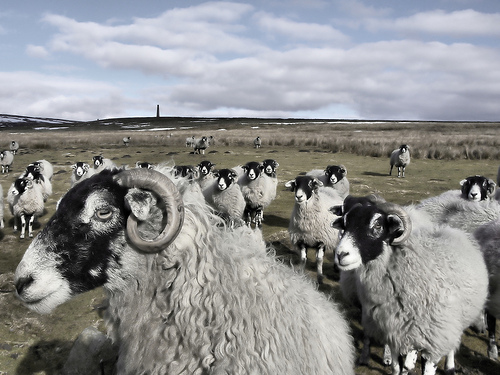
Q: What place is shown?
A: It is a field.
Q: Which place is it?
A: It is a field.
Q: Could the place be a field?
A: Yes, it is a field.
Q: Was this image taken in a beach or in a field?
A: It was taken at a field.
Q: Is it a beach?
A: No, it is a field.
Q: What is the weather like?
A: It is cloudy.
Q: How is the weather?
A: It is cloudy.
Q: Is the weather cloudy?
A: Yes, it is cloudy.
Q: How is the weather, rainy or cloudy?
A: It is cloudy.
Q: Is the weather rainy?
A: No, it is cloudy.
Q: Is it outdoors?
A: Yes, it is outdoors.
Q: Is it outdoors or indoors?
A: It is outdoors.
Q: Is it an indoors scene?
A: No, it is outdoors.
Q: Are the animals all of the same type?
A: Yes, all the animals are sheep.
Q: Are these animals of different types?
A: No, all the animals are sheep.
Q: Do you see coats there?
A: Yes, there is a coat.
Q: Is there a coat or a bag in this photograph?
A: Yes, there is a coat.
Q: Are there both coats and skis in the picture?
A: No, there is a coat but no skis.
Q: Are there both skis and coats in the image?
A: No, there is a coat but no skis.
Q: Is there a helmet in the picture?
A: No, there are no helmets.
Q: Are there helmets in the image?
A: No, there are no helmets.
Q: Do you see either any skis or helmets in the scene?
A: No, there are no helmets or skis.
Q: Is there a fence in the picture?
A: No, there are no fences.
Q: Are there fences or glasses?
A: No, there are no fences or glasses.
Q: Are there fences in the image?
A: No, there are no fences.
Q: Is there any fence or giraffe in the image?
A: No, there are no fences or giraffes.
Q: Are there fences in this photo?
A: No, there are no fences.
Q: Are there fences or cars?
A: No, there are no fences or cars.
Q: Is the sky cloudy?
A: Yes, the sky is cloudy.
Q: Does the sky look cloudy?
A: Yes, the sky is cloudy.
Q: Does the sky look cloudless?
A: No, the sky is cloudy.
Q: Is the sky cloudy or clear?
A: The sky is cloudy.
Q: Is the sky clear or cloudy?
A: The sky is cloudy.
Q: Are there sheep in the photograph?
A: Yes, there is a sheep.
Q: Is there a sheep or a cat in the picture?
A: Yes, there is a sheep.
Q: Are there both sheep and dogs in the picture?
A: No, there is a sheep but no dogs.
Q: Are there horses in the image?
A: No, there are no horses.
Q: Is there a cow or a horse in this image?
A: No, there are no horses or cows.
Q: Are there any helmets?
A: No, there are no helmets.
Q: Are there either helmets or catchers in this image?
A: No, there are no helmets or catchers.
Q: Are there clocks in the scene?
A: No, there are no clocks.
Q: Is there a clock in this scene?
A: No, there are no clocks.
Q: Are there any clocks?
A: No, there are no clocks.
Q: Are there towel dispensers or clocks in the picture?
A: No, there are no clocks or towel dispensers.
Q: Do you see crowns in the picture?
A: No, there are no crowns.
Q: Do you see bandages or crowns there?
A: No, there are no crowns or bandages.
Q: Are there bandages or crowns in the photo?
A: No, there are no crowns or bandages.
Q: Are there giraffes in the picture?
A: No, there are no giraffes.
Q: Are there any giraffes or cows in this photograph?
A: No, there are no giraffes or cows.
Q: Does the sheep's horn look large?
A: Yes, the horn is large.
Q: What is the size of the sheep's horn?
A: The horn is large.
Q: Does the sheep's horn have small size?
A: No, the horn is large.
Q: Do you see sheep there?
A: Yes, there is a sheep.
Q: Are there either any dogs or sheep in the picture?
A: Yes, there is a sheep.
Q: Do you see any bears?
A: No, there are no bears.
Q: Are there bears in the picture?
A: No, there are no bears.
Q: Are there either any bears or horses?
A: No, there are no bears or horses.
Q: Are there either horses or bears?
A: No, there are no bears or horses.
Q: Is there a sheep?
A: Yes, there is a sheep.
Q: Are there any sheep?
A: Yes, there is a sheep.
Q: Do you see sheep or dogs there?
A: Yes, there is a sheep.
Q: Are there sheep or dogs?
A: Yes, there is a sheep.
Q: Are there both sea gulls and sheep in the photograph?
A: No, there is a sheep but no seagulls.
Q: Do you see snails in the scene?
A: No, there are no snails.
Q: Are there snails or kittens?
A: No, there are no snails or kittens.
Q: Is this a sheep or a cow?
A: This is a sheep.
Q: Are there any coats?
A: Yes, there is a coat.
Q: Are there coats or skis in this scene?
A: Yes, there is a coat.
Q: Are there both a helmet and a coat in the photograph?
A: No, there is a coat but no helmets.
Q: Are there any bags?
A: No, there are no bags.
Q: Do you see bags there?
A: No, there are no bags.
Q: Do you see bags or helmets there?
A: No, there are no bags or helmets.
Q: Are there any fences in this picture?
A: No, there are no fences.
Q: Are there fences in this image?
A: No, there are no fences.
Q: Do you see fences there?
A: No, there are no fences.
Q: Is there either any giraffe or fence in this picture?
A: No, there are no fences or giraffes.